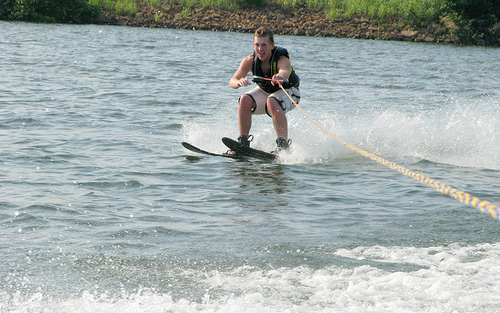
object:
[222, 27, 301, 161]
man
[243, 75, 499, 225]
tow rope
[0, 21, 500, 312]
ripples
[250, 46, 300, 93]
jacket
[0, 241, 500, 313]
wake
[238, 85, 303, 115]
trunks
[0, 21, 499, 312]
adventure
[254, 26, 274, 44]
hair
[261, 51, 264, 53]
teeth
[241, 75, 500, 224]
rope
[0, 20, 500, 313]
water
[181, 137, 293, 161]
kneboarding